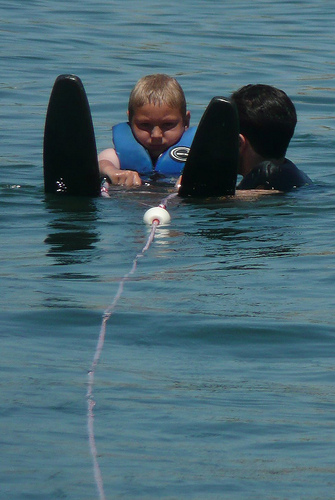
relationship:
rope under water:
[86, 257, 170, 294] [151, 36, 272, 86]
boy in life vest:
[106, 75, 203, 225] [125, 143, 192, 186]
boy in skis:
[106, 75, 203, 225] [16, 135, 104, 171]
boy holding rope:
[106, 75, 203, 225] [86, 257, 170, 294]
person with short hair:
[222, 80, 325, 194] [230, 81, 297, 158]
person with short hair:
[222, 80, 325, 194] [263, 0, 280, 142]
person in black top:
[222, 80, 325, 194] [253, 164, 301, 187]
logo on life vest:
[173, 143, 194, 161] [125, 143, 192, 186]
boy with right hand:
[106, 75, 203, 225] [102, 161, 142, 197]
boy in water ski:
[106, 75, 203, 225] [206, 125, 235, 201]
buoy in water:
[145, 196, 168, 236] [151, 36, 272, 86]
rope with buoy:
[86, 257, 170, 294] [145, 196, 168, 236]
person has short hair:
[222, 80, 325, 194] [230, 81, 297, 158]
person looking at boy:
[222, 80, 325, 194] [106, 75, 203, 225]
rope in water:
[86, 257, 170, 294] [151, 36, 272, 86]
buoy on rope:
[145, 196, 168, 236] [86, 257, 170, 294]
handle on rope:
[136, 169, 194, 201] [86, 257, 170, 294]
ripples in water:
[234, 30, 282, 47] [151, 36, 272, 86]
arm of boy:
[104, 151, 120, 157] [106, 75, 203, 225]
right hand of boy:
[102, 161, 142, 197] [106, 75, 203, 225]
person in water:
[222, 80, 325, 194] [151, 36, 272, 86]